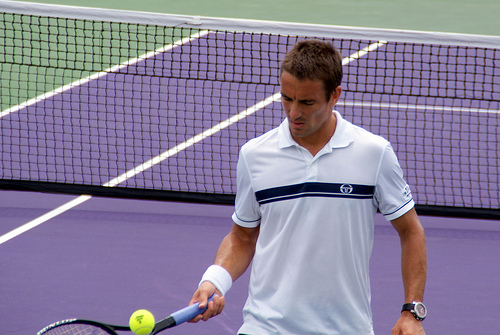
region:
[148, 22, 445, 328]
man wearing white shirt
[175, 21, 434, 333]
man wearing white wristband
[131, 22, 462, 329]
man wearing black watch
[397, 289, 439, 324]
black watch with silver face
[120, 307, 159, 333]
green tennis ball on racket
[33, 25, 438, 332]
man holding tennis racket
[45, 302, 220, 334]
tennis racket with blue tape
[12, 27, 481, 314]
purple tennis court with white lines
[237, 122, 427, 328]
white shirt with black stripe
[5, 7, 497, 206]
white tennis net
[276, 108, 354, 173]
THE MAN'S SHIRT HAS A COLLAR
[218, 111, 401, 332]
THE MAN'S SHIRT IS WHITE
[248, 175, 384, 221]
THE MAN'S SHIRT HAS A BLACK STRIPE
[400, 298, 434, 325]
THE MAN IS WEARING A WATCH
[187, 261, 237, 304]
THE MAN IS WEARING A WRIST BAND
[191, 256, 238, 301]
THE WRIST BAND IS WHITE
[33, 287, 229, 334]
THE MAN IS HOLDING A RACKET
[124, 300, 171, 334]
THE TENNIS BALL IS YELLOW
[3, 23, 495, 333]
THE COURT IS BURPLE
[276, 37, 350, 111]
THE MAN HAS SHORT HAIR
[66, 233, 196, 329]
the ball is green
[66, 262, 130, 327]
the ball is green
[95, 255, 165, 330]
the ball is green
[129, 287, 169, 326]
the ball is green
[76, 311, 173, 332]
tennis ball is yellow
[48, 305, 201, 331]
tennis ball on the tennis racket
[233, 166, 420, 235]
blue stripes on tennis shirt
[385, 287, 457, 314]
man is wearing a watch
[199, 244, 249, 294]
man is wearing a wrist band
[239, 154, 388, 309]
shirt is white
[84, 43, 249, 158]
white lines on the tennis court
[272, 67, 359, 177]
tennis player looking at the tennis ball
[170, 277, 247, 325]
handle of the racket is blue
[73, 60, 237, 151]
netting of the tennis net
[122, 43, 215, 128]
black string on net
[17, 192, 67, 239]
white line on purple court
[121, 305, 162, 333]
yellow tennis ball above racket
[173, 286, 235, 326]
hand on blue grip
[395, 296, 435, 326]
watch on man's wrist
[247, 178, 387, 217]
stripes across white shirt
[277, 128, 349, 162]
open collar of shirt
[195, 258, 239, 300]
white band on wrist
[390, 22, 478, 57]
white top of net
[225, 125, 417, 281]
short sleeved white shirt